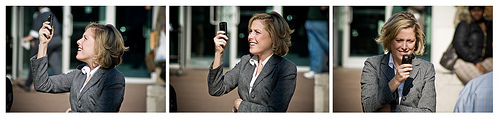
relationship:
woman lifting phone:
[28, 20, 129, 114] [46, 12, 53, 34]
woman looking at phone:
[208, 11, 300, 112] [219, 21, 227, 30]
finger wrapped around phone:
[399, 63, 414, 70] [401, 52, 411, 64]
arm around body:
[232, 97, 270, 113] [233, 55, 298, 112]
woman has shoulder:
[359, 10, 440, 112] [420, 58, 437, 77]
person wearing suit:
[19, 6, 62, 92] [30, 56, 127, 112]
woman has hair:
[28, 20, 129, 114] [85, 20, 130, 70]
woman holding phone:
[208, 11, 300, 112] [219, 21, 227, 30]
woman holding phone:
[28, 20, 129, 114] [46, 12, 53, 34]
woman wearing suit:
[28, 20, 129, 114] [30, 56, 127, 112]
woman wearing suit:
[208, 11, 300, 112] [207, 55, 297, 114]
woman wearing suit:
[359, 10, 440, 112] [361, 57, 436, 112]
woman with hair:
[208, 11, 300, 112] [246, 11, 296, 57]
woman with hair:
[28, 20, 129, 114] [85, 20, 130, 70]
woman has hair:
[359, 10, 440, 112] [375, 11, 425, 59]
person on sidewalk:
[451, 5, 496, 82] [332, 68, 465, 113]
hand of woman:
[38, 21, 54, 42] [28, 20, 129, 114]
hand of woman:
[211, 31, 230, 52] [208, 11, 300, 112]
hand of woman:
[395, 62, 414, 84] [359, 10, 440, 112]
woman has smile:
[359, 10, 440, 112] [397, 48, 412, 55]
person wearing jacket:
[451, 5, 496, 82] [454, 17, 493, 60]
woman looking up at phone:
[28, 20, 129, 114] [46, 12, 53, 34]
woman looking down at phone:
[359, 10, 440, 112] [401, 52, 411, 64]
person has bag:
[451, 5, 496, 82] [441, 44, 459, 71]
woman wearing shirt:
[28, 20, 129, 114] [81, 66, 100, 92]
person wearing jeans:
[303, 5, 331, 80] [306, 21, 331, 73]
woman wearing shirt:
[208, 11, 300, 112] [247, 55, 274, 94]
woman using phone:
[359, 10, 440, 112] [401, 52, 411, 64]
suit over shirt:
[30, 56, 127, 112] [81, 66, 100, 92]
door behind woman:
[63, 6, 117, 73] [28, 20, 129, 114]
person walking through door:
[19, 6, 62, 92] [18, 6, 70, 78]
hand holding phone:
[38, 21, 54, 42] [217, 21, 229, 41]